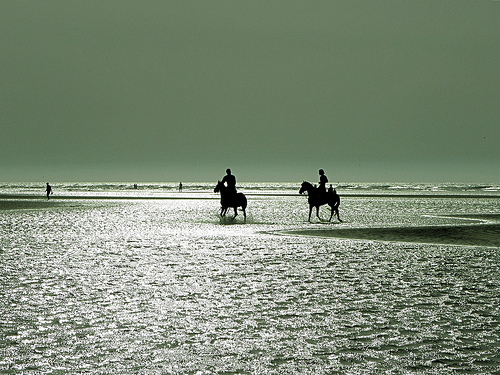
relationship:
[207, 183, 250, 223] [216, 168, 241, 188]
horse with rider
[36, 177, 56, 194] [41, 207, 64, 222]
person walking on beach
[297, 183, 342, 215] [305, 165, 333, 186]
horse with rider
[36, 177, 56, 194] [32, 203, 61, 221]
person walking in water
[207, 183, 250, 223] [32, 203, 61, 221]
horse running in water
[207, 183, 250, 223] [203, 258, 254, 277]
horse running in waves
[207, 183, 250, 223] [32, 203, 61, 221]
horse walking in water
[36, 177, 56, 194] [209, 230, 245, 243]
person walking in runing in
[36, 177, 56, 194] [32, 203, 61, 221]
person running in water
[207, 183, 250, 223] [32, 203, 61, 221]
horse in water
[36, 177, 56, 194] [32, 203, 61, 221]
person in water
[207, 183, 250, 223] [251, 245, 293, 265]
horse in watera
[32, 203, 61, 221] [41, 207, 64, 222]
water in beach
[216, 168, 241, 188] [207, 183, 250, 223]
rider on horse